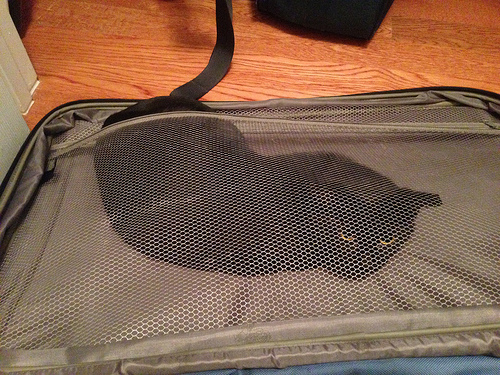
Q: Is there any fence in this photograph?
A: No, there are no fences.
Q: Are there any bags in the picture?
A: Yes, there is a bag.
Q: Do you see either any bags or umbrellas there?
A: Yes, there is a bag.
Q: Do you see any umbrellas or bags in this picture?
A: Yes, there is a bag.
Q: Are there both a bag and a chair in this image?
A: No, there is a bag but no chairs.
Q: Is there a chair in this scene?
A: No, there are no chairs.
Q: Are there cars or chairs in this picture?
A: No, there are no chairs or cars.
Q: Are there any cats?
A: Yes, there is a cat.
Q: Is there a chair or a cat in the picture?
A: Yes, there is a cat.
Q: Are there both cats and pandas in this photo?
A: No, there is a cat but no pandas.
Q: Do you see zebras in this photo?
A: No, there are no zebras.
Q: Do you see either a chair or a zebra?
A: No, there are no zebras or chairs.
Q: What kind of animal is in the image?
A: The animal is a cat.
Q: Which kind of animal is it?
A: The animal is a cat.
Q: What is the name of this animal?
A: This is a cat.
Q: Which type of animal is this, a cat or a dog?
A: This is a cat.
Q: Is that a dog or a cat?
A: That is a cat.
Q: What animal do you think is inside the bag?
A: The cat is inside the bag.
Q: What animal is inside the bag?
A: The cat is inside the bag.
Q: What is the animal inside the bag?
A: The animal is a cat.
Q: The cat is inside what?
A: The cat is inside the bag.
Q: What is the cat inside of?
A: The cat is inside the bag.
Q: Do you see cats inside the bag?
A: Yes, there is a cat inside the bag.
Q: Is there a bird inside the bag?
A: No, there is a cat inside the bag.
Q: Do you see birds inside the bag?
A: No, there is a cat inside the bag.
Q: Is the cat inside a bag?
A: Yes, the cat is inside a bag.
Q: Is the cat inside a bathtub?
A: No, the cat is inside a bag.